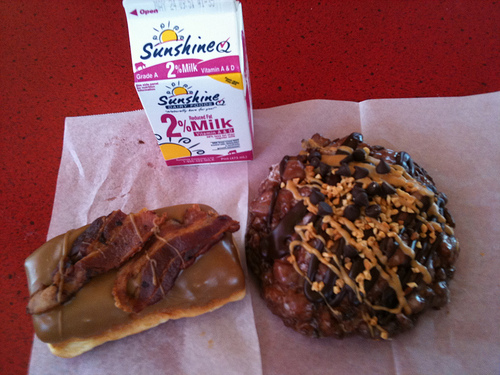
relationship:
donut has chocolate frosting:
[254, 139, 461, 337] [266, 190, 283, 215]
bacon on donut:
[87, 214, 227, 300] [254, 139, 461, 337]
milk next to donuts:
[121, 4, 264, 164] [254, 139, 461, 337]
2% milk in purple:
[165, 58, 198, 80] [202, 57, 225, 66]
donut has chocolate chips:
[254, 139, 461, 337] [342, 130, 366, 150]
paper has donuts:
[299, 99, 421, 122] [254, 139, 461, 337]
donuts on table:
[254, 139, 461, 337] [309, 35, 393, 71]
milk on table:
[121, 4, 264, 164] [309, 35, 393, 71]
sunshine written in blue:
[138, 38, 231, 60] [146, 42, 220, 53]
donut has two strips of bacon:
[254, 139, 461, 337] [87, 214, 227, 300]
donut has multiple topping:
[254, 139, 461, 337] [343, 204, 359, 219]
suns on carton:
[150, 23, 198, 165] [121, 4, 264, 164]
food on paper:
[7, 204, 275, 365] [29, 89, 499, 375]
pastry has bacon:
[7, 204, 275, 365] [87, 214, 227, 300]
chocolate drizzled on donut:
[265, 187, 292, 217] [249, 132, 458, 339]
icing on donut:
[394, 155, 423, 178] [249, 132, 458, 339]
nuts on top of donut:
[321, 174, 343, 209] [249, 132, 458, 339]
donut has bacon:
[254, 139, 461, 337] [87, 214, 227, 300]